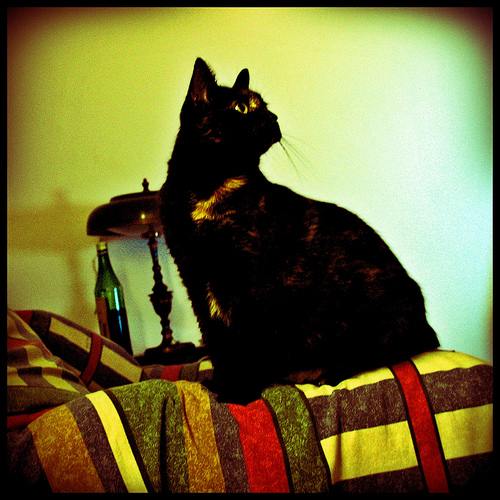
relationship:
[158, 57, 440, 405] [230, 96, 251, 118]
black cat has eye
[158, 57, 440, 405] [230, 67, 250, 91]
black cat has ear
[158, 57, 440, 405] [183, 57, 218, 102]
black cat has ear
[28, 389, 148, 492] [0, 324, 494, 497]
stripes are on quilt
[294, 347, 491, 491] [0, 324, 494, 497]
stripes are on quilt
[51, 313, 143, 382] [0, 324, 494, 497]
stripes are on quilt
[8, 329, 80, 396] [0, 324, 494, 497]
stripes are on quilt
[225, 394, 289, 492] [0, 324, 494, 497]
stripes are on quilt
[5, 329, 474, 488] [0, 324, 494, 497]
stripes are on quilt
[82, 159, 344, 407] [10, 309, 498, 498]
chair covered in a blanket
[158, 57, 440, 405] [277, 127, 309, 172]
black cat has whiskers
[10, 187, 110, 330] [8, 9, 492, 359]
shadow on wall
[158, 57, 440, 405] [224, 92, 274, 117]
black cat has eye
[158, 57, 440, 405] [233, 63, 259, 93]
black cat has ear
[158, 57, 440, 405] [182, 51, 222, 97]
black cat has ear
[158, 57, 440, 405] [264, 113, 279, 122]
black cat has nose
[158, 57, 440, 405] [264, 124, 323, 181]
black cat has whiskers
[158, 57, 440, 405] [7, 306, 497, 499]
black cat on couch